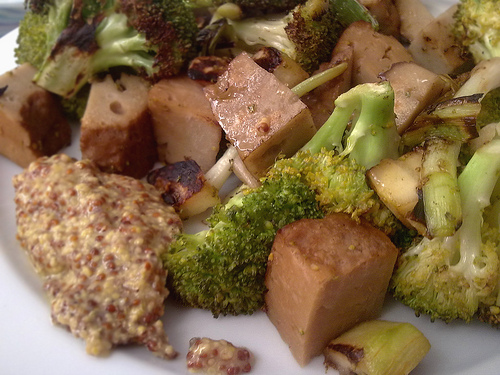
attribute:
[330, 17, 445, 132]
sausage — grilled 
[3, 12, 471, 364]
sausage — grilled 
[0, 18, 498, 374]
porcelain plate — white rounded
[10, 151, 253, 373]
mustard — large garin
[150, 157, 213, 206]
burnt veggie — square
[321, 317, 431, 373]
stem — green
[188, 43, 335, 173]
grilled sausage — grilled 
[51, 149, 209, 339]
gravy — white, brown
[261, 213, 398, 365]
sausage — dark grilled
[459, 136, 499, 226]
broccoli stem — green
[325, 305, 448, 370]
clerey — cooked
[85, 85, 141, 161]
sausage — grilled , chunk 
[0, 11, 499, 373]
plate — white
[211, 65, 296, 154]
sausage — grilled 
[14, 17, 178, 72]
broccoli — green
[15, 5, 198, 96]
broccoli — charred 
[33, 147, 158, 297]
gravy — small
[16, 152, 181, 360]
blob — big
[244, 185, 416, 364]
tofu — cooked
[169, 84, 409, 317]
broccoli — large, green, cooked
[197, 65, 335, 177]
meat — large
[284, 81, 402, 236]
broccoli — upside down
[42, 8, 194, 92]
broccol piece — brown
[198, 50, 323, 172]
meat — wet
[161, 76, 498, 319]
broccoli — fried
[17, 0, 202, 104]
broccoli — large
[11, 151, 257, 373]
gravy — speckled